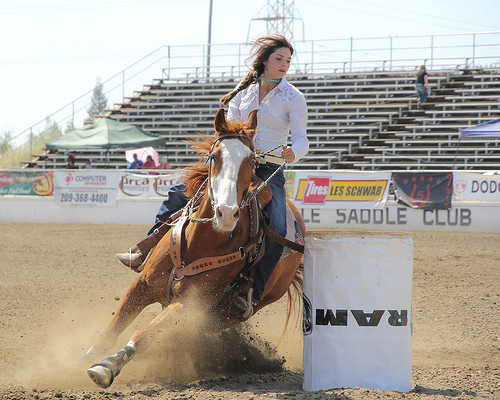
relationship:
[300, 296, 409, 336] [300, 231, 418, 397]
logo on barrel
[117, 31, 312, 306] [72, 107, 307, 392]
woman on horse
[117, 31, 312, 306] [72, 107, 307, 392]
woman racing horse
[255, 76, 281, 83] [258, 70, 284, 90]
necklace around neck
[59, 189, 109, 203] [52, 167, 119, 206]
number on advertisement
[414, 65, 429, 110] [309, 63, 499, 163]
woman walking on stands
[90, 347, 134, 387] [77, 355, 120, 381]
straps on hoof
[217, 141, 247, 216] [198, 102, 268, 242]
white patch on head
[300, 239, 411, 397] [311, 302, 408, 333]
barrel with writing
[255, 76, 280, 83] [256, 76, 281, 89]
necklace on neck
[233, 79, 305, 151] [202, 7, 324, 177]
shirt on woman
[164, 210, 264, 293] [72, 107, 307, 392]
bridle on horse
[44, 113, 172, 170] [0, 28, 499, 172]
tent in stands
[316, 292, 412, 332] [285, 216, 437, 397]
word on obsticle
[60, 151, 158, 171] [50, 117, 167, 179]
people under tent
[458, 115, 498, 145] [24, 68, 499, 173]
tent in bleachers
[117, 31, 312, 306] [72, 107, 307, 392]
woman riding horse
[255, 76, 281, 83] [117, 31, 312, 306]
necklace on woman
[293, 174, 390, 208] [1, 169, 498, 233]
advertisement on wall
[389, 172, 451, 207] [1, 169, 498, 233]
advertisement on wall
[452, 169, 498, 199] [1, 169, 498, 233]
advertisement on wall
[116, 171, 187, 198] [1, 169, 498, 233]
advertisement on wall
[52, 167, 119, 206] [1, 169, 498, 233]
advertisement on wall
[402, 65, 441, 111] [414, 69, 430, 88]
woman in shirt